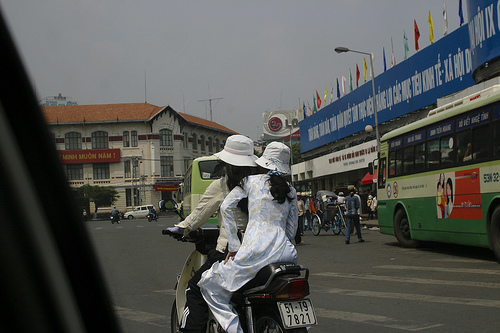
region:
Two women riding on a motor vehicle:
[164, 133, 319, 331]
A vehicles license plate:
[276, 294, 314, 327]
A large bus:
[375, 84, 498, 248]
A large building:
[42, 103, 235, 219]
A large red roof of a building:
[40, 102, 237, 132]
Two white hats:
[212, 132, 295, 176]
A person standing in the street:
[341, 186, 363, 241]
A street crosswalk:
[116, 253, 498, 326]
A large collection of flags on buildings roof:
[290, 3, 465, 124]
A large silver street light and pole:
[330, 45, 380, 158]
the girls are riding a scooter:
[206, 130, 311, 303]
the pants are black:
[186, 282, 201, 313]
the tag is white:
[276, 299, 321, 328]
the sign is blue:
[321, 112, 352, 134]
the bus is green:
[413, 209, 436, 228]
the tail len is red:
[286, 278, 311, 301]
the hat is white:
[267, 145, 287, 170]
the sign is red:
[267, 116, 282, 131]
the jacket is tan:
[201, 187, 225, 202]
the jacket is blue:
[343, 197, 358, 211]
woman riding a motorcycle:
[87, 103, 397, 328]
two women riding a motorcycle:
[127, 91, 323, 330]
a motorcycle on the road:
[129, 145, 351, 317]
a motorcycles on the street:
[132, 118, 400, 329]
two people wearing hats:
[154, 116, 312, 319]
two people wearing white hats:
[162, 108, 347, 320]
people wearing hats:
[179, 113, 297, 271]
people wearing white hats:
[198, 127, 325, 254]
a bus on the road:
[352, 68, 497, 293]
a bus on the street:
[341, 81, 496, 211]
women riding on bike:
[165, 135, 330, 331]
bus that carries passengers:
[373, 76, 498, 273]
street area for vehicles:
[96, 232, 158, 270]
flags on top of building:
[291, 3, 463, 117]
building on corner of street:
[37, 79, 222, 213]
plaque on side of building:
[60, 139, 127, 167]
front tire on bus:
[387, 203, 419, 245]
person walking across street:
[339, 186, 367, 244]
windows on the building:
[60, 129, 116, 146]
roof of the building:
[51, 105, 150, 124]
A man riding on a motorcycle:
[102, 202, 125, 223]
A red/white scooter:
[150, 212, 315, 327]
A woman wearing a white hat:
[165, 125, 261, 325]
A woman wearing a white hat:
[190, 135, 305, 325]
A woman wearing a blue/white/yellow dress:
[191, 140, 301, 330]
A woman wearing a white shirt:
[170, 120, 260, 326]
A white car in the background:
[120, 197, 157, 222]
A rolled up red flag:
[405, 10, 425, 50]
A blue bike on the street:
[300, 190, 345, 240]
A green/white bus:
[370, 81, 496, 259]